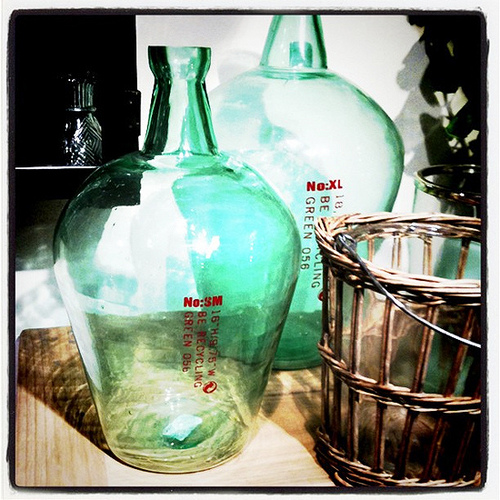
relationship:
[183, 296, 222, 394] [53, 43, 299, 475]
print on bottle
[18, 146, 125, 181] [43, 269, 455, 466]
shelf among table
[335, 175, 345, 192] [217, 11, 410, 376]
l on jar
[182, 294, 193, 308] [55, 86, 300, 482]
letter n on jar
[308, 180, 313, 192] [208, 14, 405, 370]
n on bottle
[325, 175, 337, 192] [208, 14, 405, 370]
letter x on bottle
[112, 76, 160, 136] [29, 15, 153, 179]
black hinge on cabinet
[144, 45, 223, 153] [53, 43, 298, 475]
neck on bottle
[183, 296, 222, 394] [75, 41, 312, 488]
print on glass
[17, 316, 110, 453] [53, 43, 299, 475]
shadow on bottle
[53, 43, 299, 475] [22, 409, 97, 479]
bottle on table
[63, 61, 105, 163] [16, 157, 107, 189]
vase on shelf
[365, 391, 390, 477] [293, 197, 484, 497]
straw on basket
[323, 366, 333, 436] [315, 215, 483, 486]
straw on basket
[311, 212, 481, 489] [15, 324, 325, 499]
basket on table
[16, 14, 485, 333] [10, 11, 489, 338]
shadow on wall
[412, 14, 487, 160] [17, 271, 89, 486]
plant on table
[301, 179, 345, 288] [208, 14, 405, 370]
print on bottle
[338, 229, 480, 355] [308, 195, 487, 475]
handle on basket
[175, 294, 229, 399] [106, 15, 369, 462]
print on bottles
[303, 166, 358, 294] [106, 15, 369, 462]
print on bottles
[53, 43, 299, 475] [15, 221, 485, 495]
bottle on table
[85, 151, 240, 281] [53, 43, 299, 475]
reflection on bottle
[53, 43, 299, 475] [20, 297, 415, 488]
bottle on table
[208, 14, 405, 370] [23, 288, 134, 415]
bottle on table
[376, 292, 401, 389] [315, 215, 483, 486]
straw on basket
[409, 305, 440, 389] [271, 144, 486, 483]
straw on basket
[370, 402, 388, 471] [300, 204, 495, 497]
straw on basket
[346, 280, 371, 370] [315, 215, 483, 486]
straw on basket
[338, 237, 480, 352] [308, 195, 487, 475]
handle on basket